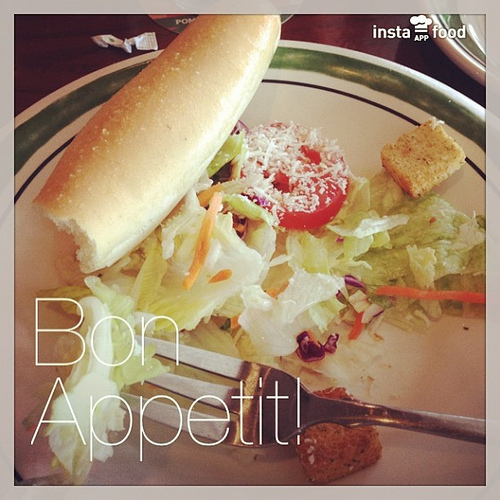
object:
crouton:
[293, 417, 390, 486]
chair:
[245, 126, 325, 163]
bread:
[34, 14, 284, 273]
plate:
[456, 321, 475, 336]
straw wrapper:
[90, 30, 159, 53]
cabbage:
[294, 329, 339, 364]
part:
[410, 334, 472, 391]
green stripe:
[12, 31, 482, 208]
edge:
[401, 67, 441, 87]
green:
[286, 52, 346, 69]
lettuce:
[366, 211, 454, 272]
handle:
[252, 363, 439, 451]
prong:
[127, 344, 239, 376]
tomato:
[242, 125, 352, 229]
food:
[25, 33, 477, 475]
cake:
[309, 436, 379, 457]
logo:
[356, 9, 473, 64]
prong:
[116, 399, 239, 455]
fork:
[105, 324, 487, 491]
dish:
[19, 29, 484, 490]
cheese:
[241, 125, 346, 228]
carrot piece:
[374, 285, 484, 306]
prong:
[143, 362, 233, 405]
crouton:
[376, 121, 466, 198]